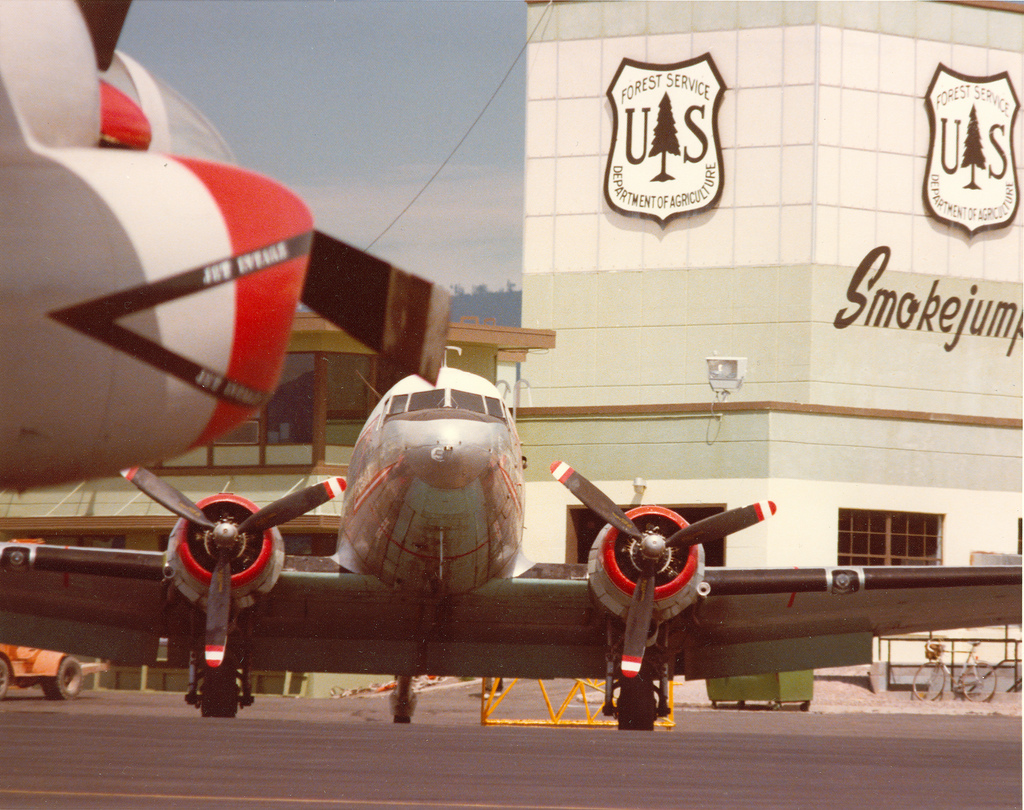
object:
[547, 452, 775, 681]
engine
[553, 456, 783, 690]
propeller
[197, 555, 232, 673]
blade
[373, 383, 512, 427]
windows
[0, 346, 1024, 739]
airplane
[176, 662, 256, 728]
wheel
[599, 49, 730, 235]
sign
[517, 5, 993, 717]
building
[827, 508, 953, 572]
windows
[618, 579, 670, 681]
propeller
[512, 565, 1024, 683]
wing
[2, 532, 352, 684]
wing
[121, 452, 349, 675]
propellor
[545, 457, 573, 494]
tips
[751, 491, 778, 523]
tips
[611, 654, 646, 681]
tips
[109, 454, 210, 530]
propeller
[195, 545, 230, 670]
propeller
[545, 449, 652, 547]
propeller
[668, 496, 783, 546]
propeller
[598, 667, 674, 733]
wheel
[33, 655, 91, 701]
wheel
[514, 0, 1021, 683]
airport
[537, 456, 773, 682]
engine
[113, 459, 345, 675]
engine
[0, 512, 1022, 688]
wings